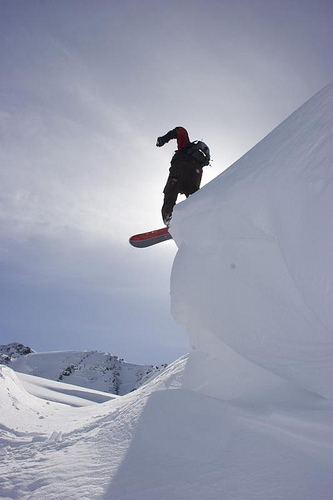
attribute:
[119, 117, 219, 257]
snowboarder — going, performing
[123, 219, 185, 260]
snowboard — grey, red, black, short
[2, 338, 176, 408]
hills — covered, low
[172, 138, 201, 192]
backpack — black, grey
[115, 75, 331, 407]
drift — large, snow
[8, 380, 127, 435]
valley — small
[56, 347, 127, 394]
trees — distant, small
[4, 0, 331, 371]
sky — white, blue, grey, cloudy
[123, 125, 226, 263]
person — performing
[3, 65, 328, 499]
snow — white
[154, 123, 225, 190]
jacket — red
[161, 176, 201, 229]
pants — black, snowpants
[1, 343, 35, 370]
rock — showing